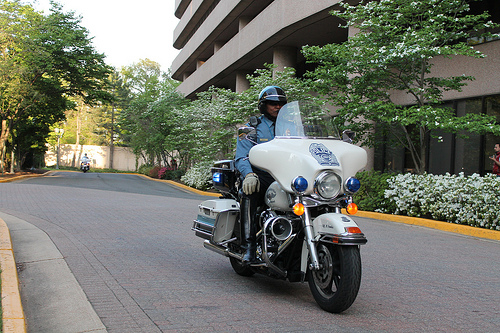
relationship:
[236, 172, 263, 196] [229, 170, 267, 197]
hand in glove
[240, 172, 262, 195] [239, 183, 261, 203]
hand on knee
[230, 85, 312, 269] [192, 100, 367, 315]
officer riding cycle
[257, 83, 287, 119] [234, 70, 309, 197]
helmet on officer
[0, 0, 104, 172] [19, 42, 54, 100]
tree with leaves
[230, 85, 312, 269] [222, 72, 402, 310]
officer on patrol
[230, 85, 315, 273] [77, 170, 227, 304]
officer headed downhill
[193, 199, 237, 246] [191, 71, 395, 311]
cargo space on cycle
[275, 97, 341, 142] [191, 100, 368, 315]
windshield of cycle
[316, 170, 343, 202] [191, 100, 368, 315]
headlight on cycle